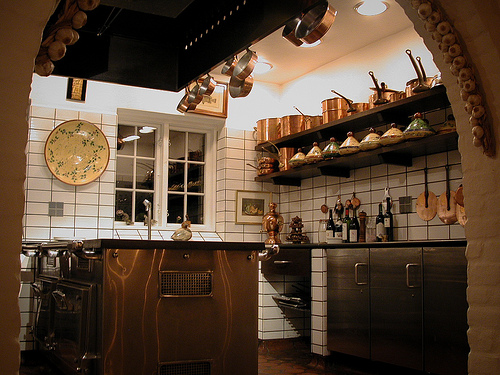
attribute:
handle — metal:
[404, 262, 416, 289]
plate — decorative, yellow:
[44, 118, 110, 186]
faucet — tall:
[143, 197, 155, 239]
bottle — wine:
[383, 196, 394, 243]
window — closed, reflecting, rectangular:
[114, 115, 220, 233]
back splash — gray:
[283, 144, 465, 242]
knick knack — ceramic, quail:
[170, 220, 193, 241]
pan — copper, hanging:
[294, 2, 337, 44]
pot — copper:
[254, 117, 282, 143]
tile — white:
[74, 191, 99, 206]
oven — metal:
[52, 280, 93, 374]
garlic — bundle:
[34, 0, 100, 77]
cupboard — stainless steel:
[324, 247, 369, 361]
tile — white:
[225, 168, 246, 182]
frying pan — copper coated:
[405, 80, 432, 99]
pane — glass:
[167, 159, 187, 194]